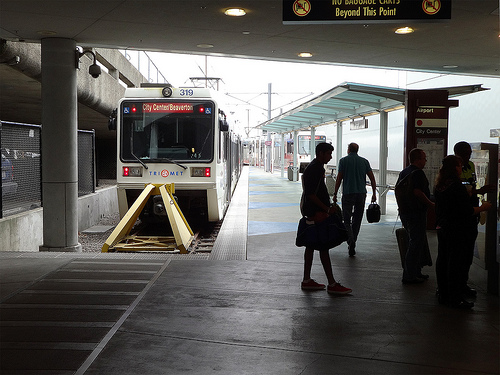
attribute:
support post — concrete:
[26, 37, 112, 254]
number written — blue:
[148, 168, 184, 179]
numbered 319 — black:
[176, 86, 205, 105]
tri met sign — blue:
[141, 161, 194, 187]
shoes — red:
[287, 272, 361, 305]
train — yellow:
[93, 142, 214, 299]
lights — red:
[112, 91, 227, 173]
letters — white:
[144, 94, 186, 130]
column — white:
[74, 51, 107, 122]